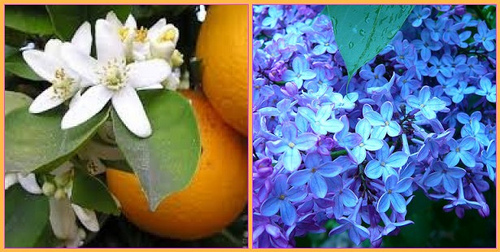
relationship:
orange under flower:
[107, 87, 248, 240] [49, 21, 169, 139]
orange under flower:
[194, 5, 246, 133] [49, 21, 169, 139]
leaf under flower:
[110, 88, 202, 211] [49, 21, 169, 139]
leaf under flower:
[5, 103, 113, 172] [49, 21, 169, 139]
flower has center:
[49, 21, 169, 139] [99, 62, 131, 92]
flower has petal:
[49, 21, 169, 139] [94, 18, 129, 69]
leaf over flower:
[327, 7, 417, 97] [397, 68, 421, 98]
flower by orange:
[49, 21, 169, 139] [194, 5, 246, 133]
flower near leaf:
[397, 68, 421, 98] [327, 7, 417, 97]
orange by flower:
[194, 5, 246, 133] [49, 21, 169, 139]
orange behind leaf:
[107, 87, 248, 240] [110, 88, 202, 211]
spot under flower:
[373, 53, 402, 79] [397, 68, 421, 98]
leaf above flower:
[327, 7, 417, 97] [397, 68, 421, 98]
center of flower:
[99, 62, 131, 92] [49, 21, 169, 139]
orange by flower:
[194, 5, 246, 133] [22, 21, 96, 113]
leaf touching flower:
[110, 88, 202, 211] [49, 21, 169, 139]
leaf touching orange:
[110, 88, 202, 211] [107, 87, 248, 240]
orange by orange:
[107, 87, 248, 240] [194, 5, 246, 133]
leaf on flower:
[110, 88, 202, 211] [49, 21, 169, 139]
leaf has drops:
[327, 7, 417, 97] [348, 41, 355, 51]